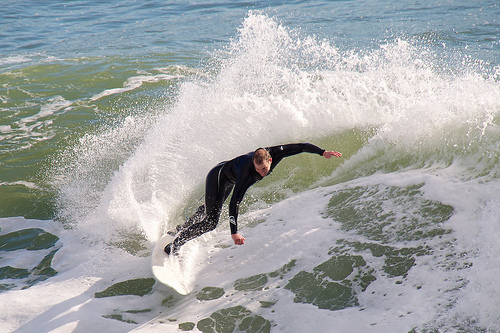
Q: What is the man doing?
A: Surfing.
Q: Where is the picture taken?
A: The ocean.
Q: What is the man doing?
A: Surfboard.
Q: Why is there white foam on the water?
A: From crashing waves.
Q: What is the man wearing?
A: A wet suit.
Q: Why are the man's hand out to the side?
A: For balance.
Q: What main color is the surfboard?
A: White.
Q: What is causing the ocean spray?
A: Surfboard cutting through wave.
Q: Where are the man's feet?
A: On surfboard.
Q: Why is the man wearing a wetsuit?
A: To stay dry and warm.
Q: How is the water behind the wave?
A: Calm.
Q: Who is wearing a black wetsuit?
A: Surfer.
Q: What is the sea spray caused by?
A: Rough surf.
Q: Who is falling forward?
A: A surfer.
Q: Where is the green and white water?
A: Ocean.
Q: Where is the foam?
A: Ocean water.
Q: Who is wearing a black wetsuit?
A: A surfer.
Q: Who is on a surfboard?
A: A surfer.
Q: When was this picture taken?
A: Daytime.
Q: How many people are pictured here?
A: One.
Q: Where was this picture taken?
A: The ocean.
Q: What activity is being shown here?
A: Surfing.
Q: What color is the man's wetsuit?
A: Black.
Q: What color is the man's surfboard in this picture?
A: White.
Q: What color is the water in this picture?
A: Blue.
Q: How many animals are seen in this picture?
A: Zero.